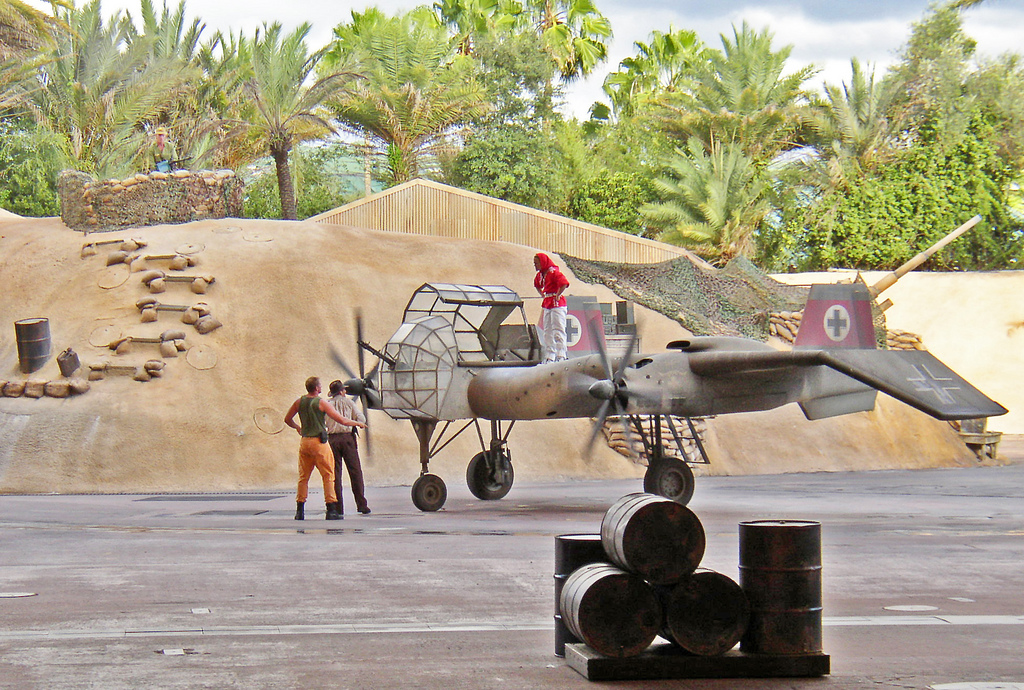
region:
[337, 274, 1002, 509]
Airplane on a airfield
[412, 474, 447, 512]
Tire on a plane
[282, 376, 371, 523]
Men standing on an airfield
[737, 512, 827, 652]
Oil drum sitting on airfield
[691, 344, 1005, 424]
Wing on an airplane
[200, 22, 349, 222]
Palm tree behind a hill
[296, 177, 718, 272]
Roof top behind a hill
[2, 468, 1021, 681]
Airfield in front of a hill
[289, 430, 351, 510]
Man wearing pants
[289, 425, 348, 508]
Man is wearing pants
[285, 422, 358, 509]
Man wearing orange pants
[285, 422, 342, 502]
Man is wearing orange pants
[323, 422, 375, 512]
Man wearing brown pants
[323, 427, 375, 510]
Man is wearing brown pants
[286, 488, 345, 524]
Man wearing shoes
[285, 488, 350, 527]
Man wearing black shoes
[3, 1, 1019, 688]
a setting in what looks like a movie set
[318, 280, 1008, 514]
an airplane with a vintage appearance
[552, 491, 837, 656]
a grouping of metal barrels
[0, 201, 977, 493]
a large brown mound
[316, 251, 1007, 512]
woman standing on top of plane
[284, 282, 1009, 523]
two men standing near propeller of plane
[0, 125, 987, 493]
person standing within enclosed area on top of hill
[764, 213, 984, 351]
large light brown gun barrel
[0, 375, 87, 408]
a step on a stairway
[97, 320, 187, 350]
a step on a stairway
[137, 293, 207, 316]
a step on a stairway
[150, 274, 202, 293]
a step on a stairway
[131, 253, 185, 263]
a step on a stairway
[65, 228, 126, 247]
a step on a stairway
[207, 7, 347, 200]
a tree in a field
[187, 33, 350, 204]
a tree in a field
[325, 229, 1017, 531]
a man is on a plane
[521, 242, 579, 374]
man wears red top and white pants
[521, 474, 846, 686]
cylindres on a pile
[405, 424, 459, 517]
front wheel of a plane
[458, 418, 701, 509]
two back wheels of a plane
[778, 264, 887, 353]
a black cross on a vertical stabilizer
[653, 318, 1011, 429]
two horizontal stabilizers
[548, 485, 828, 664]
Metal Barrels on a pallet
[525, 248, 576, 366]
Person in red standing on an airplane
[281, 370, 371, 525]
man with green sleeveless shirt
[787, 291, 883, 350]
red decal on the rudder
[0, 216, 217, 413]
stone steps leading up the hill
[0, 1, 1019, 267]
tress on the top of the hill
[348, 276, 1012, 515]
old nazi airplane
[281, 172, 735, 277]
top of a building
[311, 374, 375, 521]
man in a fidora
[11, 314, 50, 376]
metal barrel on the hill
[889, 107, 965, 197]
green leaves on the tree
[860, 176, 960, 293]
green leaves on the tree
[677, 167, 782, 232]
green leaves on the tree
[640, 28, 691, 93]
green leaves on the tree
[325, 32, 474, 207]
A tree in a city.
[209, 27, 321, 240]
A tree in a city.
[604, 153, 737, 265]
A tree in a city.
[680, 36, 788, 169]
A tree in a city.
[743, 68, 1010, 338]
A tree in a city.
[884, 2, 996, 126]
A tree in a city.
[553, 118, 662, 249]
A tree in a city.